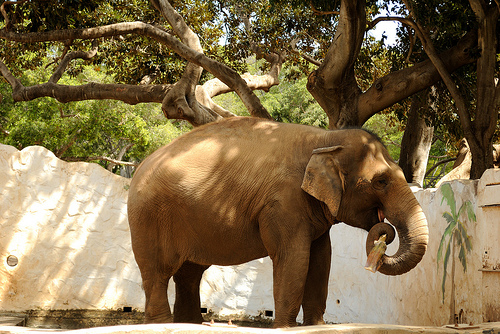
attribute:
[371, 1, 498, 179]
tree — thick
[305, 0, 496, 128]
tree — thick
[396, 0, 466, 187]
tree — thick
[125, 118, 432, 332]
elephant — brown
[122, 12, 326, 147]
branch — large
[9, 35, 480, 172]
trees — gray, brown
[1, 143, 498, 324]
wall — stucca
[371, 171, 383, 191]
eye — brown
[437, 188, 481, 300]
painting — palm tree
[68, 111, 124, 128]
leaves — green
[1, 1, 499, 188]
trees — gray, brown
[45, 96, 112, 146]
leaves — green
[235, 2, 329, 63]
leaves — green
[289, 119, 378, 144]
hair — dark, brown